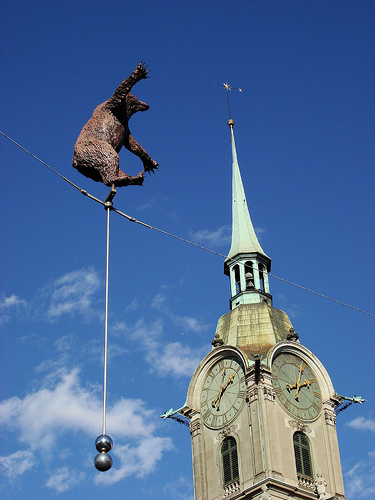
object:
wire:
[82, 192, 87, 193]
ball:
[94, 452, 113, 472]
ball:
[94, 434, 113, 454]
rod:
[102, 207, 111, 436]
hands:
[286, 379, 313, 394]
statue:
[313, 469, 327, 498]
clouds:
[0, 223, 228, 382]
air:
[315, 138, 316, 143]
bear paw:
[132, 61, 152, 83]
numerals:
[202, 386, 210, 393]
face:
[200, 360, 245, 428]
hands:
[216, 367, 227, 411]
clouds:
[0, 374, 176, 496]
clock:
[271, 353, 324, 423]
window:
[218, 433, 239, 488]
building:
[159, 81, 367, 500]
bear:
[71, 59, 161, 186]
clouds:
[344, 405, 375, 499]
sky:
[0, 0, 375, 500]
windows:
[292, 429, 314, 484]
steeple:
[221, 79, 275, 307]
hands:
[294, 359, 305, 403]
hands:
[210, 371, 235, 409]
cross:
[214, 81, 241, 119]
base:
[104, 184, 117, 212]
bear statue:
[71, 61, 160, 186]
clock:
[199, 357, 248, 428]